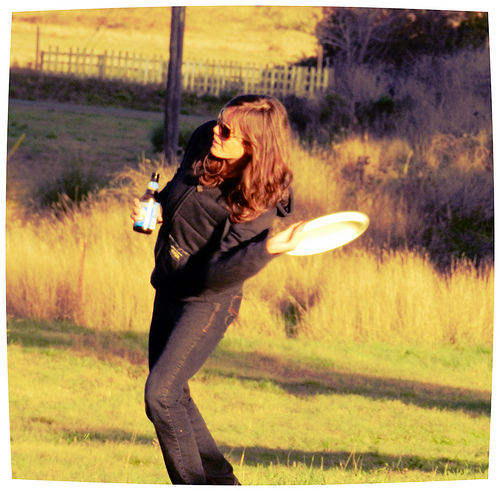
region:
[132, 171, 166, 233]
a bottle of beer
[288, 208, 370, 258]
white frisbee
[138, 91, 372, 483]
woman with a beer throwing a frisbee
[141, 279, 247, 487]
dark wash blue jeans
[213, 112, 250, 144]
sunglasses on her face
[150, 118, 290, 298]
a black jacket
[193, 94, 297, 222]
long brown hair with bangs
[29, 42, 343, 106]
wooden fence in the background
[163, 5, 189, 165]
wooden telephone pole in the background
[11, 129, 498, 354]
tall grass behind her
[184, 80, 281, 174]
a woman wearing sunglasses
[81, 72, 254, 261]
a woman holding a bottle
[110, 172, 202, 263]
a bottle of beer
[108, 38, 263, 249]
a woman holding a bottle of beer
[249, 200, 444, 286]
a frisbee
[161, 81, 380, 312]
a woman holding a frisbee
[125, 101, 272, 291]
a woman wearing a black jacket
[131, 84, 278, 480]
a woman wearing jeans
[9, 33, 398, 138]
a white fence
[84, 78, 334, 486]
a woman standing on grass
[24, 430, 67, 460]
Patch of long green grass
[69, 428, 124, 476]
Patch of long green grass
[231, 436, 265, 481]
Patch of long green grass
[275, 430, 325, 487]
Patch of long green grass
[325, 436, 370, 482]
Patch of long green grass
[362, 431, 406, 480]
Patch of long green grass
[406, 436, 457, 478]
Patch of long green grass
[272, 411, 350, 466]
Patch of long green grass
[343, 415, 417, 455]
Patch of long green grass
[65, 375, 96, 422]
Patch of long green grass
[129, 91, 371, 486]
woman playing frisbee in a field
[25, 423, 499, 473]
shadow in the grass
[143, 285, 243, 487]
pair of dark blue jeans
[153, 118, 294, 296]
blue zipped hooded jacket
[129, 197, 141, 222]
fingers on a bottle of beer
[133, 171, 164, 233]
bottle of beer with a blue label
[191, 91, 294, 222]
soft long brown hair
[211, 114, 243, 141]
pair of dark sunglasses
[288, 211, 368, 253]
white frisbee about to be thrown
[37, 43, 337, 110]
long white picket fence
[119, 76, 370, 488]
woman throwing a frisbee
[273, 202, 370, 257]
the frisbee is white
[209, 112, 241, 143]
woman is wearing sunglasses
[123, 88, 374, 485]
woman holding a beer bottle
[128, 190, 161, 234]
blue label on bottle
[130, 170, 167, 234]
the bottle is brown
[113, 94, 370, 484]
woman wearing blue jeans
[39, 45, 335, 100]
the fence is white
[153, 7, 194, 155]
wooden pole in background